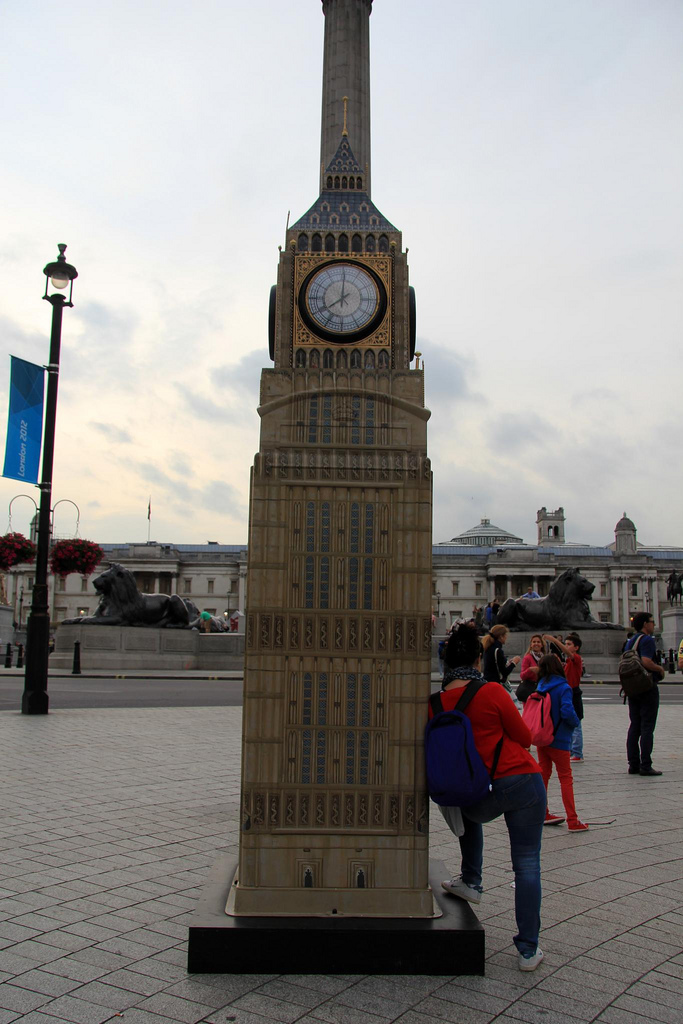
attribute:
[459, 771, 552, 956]
jeans — blue, denim, tight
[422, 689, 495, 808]
bag — blue, black, fabric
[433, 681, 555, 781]
sweater — red, long sleeved, smooth, fabric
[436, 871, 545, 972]
shoes — white, sneakers, feminine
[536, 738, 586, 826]
pants — red, feminine, tight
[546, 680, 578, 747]
jacket — blue, feminine, fabric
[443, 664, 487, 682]
scarf — black dots, gray, smooth, small, thin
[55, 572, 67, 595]
window — small, rectangular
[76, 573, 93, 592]
window — short, small, rectangular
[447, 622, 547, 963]
person — head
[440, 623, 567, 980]
person — head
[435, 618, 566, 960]
person — head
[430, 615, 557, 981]
person — head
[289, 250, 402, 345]
clock — tower